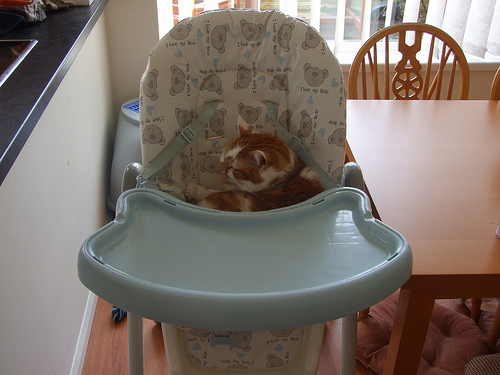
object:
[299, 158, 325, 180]
ground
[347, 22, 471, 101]
chair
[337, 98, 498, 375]
table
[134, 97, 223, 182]
strap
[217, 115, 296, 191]
head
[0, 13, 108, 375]
smooth wall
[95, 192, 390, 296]
table surface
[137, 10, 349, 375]
chair cushion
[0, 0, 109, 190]
counter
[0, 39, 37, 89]
sink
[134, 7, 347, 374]
car seat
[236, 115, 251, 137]
ear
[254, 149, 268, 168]
ear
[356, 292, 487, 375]
cushion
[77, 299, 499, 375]
floor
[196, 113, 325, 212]
animal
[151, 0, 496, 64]
blinds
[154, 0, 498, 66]
windows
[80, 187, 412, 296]
tray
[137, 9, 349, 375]
cushion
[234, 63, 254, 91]
print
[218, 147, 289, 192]
stripe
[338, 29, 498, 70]
slats